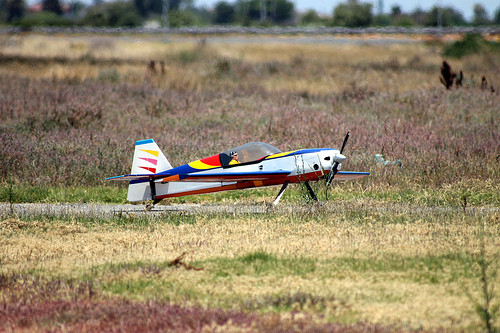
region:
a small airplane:
[96, 128, 383, 208]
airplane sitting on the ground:
[104, 126, 369, 218]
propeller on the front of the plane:
[311, 118, 378, 190]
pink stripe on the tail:
[133, 150, 161, 165]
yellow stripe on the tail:
[136, 143, 166, 156]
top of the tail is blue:
[130, 133, 161, 146]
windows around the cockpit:
[219, 135, 279, 163]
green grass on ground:
[112, 258, 149, 306]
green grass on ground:
[215, 255, 242, 284]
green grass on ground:
[246, 246, 265, 272]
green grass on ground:
[279, 246, 309, 288]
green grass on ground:
[324, 250, 371, 291]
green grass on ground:
[384, 234, 416, 281]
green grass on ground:
[298, 279, 340, 319]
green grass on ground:
[379, 167, 411, 199]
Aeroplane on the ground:
[102, 129, 377, 219]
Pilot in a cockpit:
[221, 139, 278, 167]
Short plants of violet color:
[0, 277, 355, 332]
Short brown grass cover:
[6, 214, 499, 302]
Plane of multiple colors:
[102, 130, 372, 215]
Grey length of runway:
[0, 197, 499, 219]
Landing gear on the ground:
[136, 201, 163, 213]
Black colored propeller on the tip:
[321, 128, 353, 192]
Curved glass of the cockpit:
[220, 139, 281, 166]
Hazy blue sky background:
[16, 0, 498, 22]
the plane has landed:
[118, 127, 372, 218]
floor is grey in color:
[221, 222, 324, 267]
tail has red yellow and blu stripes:
[136, 135, 168, 173]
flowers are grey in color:
[304, 103, 391, 139]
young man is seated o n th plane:
[188, 127, 308, 197]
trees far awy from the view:
[276, 4, 408, 31]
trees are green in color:
[285, 1, 387, 38]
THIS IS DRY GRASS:
[46, 104, 69, 133]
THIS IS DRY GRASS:
[420, 110, 478, 147]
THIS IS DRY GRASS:
[319, 87, 411, 113]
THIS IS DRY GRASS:
[91, 70, 233, 141]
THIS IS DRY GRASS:
[12, 220, 34, 272]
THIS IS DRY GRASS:
[92, 219, 114, 253]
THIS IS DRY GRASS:
[218, 240, 251, 271]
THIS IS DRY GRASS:
[324, 224, 378, 252]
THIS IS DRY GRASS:
[364, 293, 391, 306]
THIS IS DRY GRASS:
[295, 232, 397, 254]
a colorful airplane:
[107, 129, 372, 211]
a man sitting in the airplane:
[219, 142, 249, 172]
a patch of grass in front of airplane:
[70, 252, 494, 309]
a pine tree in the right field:
[431, 52, 463, 96]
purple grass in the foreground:
[3, 264, 266, 328]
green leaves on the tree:
[457, 33, 469, 46]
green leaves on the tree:
[332, 3, 375, 26]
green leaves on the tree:
[234, 1, 255, 23]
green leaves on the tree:
[212, 3, 231, 23]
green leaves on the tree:
[157, 1, 189, 28]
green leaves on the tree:
[472, 2, 485, 29]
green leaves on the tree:
[145, 3, 155, 10]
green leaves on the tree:
[108, 2, 138, 24]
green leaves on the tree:
[27, 7, 71, 22]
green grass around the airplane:
[387, 102, 434, 164]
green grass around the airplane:
[367, 268, 396, 310]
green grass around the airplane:
[180, 259, 244, 298]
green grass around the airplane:
[192, 103, 226, 121]